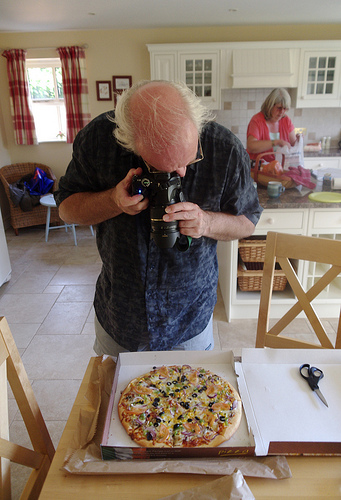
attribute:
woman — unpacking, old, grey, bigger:
[245, 79, 299, 157]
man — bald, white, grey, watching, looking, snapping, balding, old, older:
[67, 95, 250, 310]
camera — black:
[137, 171, 195, 241]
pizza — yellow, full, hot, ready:
[134, 365, 244, 448]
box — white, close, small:
[104, 343, 274, 475]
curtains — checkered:
[5, 41, 84, 129]